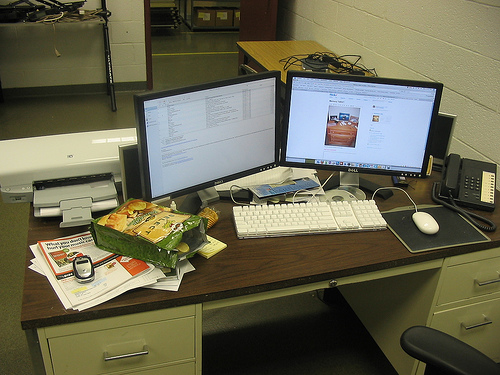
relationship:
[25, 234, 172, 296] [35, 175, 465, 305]
papers on desk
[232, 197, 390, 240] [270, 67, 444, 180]
keyboard on computer monitor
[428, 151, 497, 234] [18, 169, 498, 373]
phone on desk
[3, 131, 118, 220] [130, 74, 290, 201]
printe on computer monitor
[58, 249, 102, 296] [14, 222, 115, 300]
flip phone on pile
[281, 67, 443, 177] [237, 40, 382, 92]
computer monitor on table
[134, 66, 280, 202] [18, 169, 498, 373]
computer monitor on desk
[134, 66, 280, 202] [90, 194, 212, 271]
computer monitor next to chips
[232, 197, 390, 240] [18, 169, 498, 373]
keyboard on desk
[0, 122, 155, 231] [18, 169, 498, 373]
printe on desk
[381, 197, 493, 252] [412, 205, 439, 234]
mouse pad under mouse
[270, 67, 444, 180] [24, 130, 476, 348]
computer monitor on desk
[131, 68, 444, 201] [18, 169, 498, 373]
monitor on desk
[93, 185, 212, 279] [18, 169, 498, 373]
crackers on desk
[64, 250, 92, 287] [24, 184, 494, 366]
phone on desk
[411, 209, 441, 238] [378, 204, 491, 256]
mouse on mouse pad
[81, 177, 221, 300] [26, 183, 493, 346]
bag on desk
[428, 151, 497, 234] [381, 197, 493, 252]
phone next to mouse pad